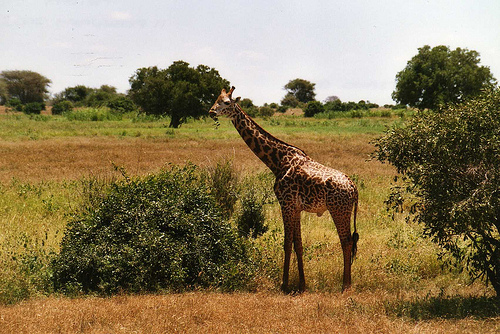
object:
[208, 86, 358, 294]
giraffe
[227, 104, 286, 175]
neck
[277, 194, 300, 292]
legs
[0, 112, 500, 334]
ground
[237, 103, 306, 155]
mane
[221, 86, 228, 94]
horns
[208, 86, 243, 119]
giraffe's head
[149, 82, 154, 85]
leaf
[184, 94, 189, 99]
leaf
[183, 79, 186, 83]
leaf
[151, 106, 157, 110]
leaf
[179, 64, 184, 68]
leaf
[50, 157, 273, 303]
bush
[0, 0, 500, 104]
cloudy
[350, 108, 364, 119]
bush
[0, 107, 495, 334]
field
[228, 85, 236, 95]
horn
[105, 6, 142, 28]
cloud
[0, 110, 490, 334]
grass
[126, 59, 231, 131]
tree